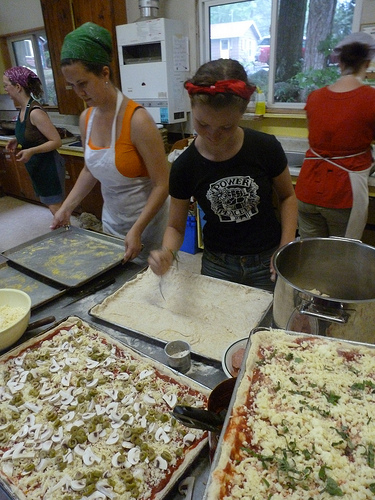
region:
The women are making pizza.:
[9, 13, 330, 368]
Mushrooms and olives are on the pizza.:
[0, 304, 199, 497]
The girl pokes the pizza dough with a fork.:
[83, 206, 293, 372]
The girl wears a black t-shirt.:
[153, 121, 293, 264]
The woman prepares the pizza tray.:
[0, 14, 154, 294]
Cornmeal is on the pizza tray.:
[5, 223, 148, 293]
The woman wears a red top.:
[294, 77, 373, 205]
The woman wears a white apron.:
[79, 81, 173, 242]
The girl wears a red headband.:
[171, 70, 266, 103]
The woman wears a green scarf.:
[51, 15, 118, 69]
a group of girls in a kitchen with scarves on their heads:
[7, 17, 373, 224]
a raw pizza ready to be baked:
[243, 321, 370, 497]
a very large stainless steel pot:
[262, 226, 373, 332]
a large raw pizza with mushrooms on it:
[7, 345, 215, 495]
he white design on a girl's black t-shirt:
[200, 175, 265, 224]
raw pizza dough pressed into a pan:
[86, 261, 266, 361]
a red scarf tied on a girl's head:
[182, 74, 253, 108]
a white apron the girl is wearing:
[72, 107, 156, 238]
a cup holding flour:
[156, 335, 195, 377]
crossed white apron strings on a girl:
[303, 133, 366, 184]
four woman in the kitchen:
[1, 30, 373, 200]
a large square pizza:
[5, 314, 205, 496]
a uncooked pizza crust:
[96, 282, 266, 371]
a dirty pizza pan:
[12, 218, 130, 290]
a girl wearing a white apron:
[52, 31, 160, 213]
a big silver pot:
[270, 226, 372, 337]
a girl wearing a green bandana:
[56, 18, 110, 110]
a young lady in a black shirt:
[167, 57, 292, 269]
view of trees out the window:
[192, 2, 367, 123]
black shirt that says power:
[175, 148, 274, 246]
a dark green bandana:
[46, 11, 115, 72]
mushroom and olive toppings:
[50, 381, 173, 457]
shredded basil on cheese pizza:
[252, 438, 347, 494]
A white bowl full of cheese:
[1, 280, 33, 352]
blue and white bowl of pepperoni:
[223, 327, 251, 385]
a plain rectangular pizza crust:
[102, 256, 254, 384]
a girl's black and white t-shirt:
[163, 124, 307, 267]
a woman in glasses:
[1, 58, 82, 224]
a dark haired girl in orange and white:
[54, 12, 180, 261]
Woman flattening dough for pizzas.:
[135, 60, 300, 369]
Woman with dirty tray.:
[33, 17, 164, 292]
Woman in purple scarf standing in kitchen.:
[0, 60, 71, 198]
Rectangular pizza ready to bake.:
[1, 302, 226, 492]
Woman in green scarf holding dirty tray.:
[38, 15, 143, 122]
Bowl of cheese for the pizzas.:
[1, 273, 34, 349]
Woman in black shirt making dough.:
[167, 73, 304, 302]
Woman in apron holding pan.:
[60, 103, 190, 286]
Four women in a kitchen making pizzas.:
[5, 23, 359, 238]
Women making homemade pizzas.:
[5, 243, 374, 382]